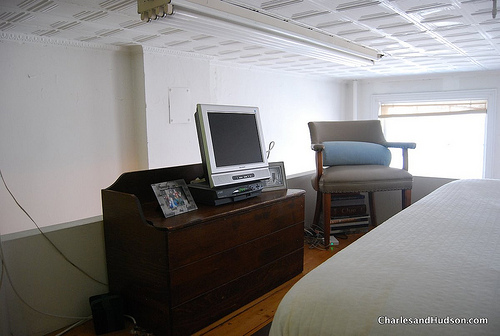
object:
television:
[189, 103, 270, 190]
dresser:
[100, 161, 307, 335]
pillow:
[314, 140, 391, 165]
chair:
[307, 120, 416, 250]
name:
[375, 314, 489, 326]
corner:
[363, 286, 499, 335]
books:
[317, 191, 370, 236]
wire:
[1, 172, 101, 336]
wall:
[1, 32, 347, 335]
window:
[378, 100, 488, 181]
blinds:
[375, 99, 487, 118]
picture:
[161, 185, 190, 209]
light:
[330, 243, 334, 246]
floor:
[33, 235, 371, 336]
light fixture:
[137, 0, 384, 71]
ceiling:
[0, 0, 499, 81]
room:
[0, 1, 500, 335]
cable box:
[187, 178, 264, 207]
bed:
[267, 178, 500, 336]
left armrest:
[382, 139, 417, 172]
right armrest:
[310, 142, 325, 184]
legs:
[310, 189, 412, 250]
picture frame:
[151, 179, 198, 218]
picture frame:
[262, 160, 286, 192]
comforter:
[270, 178, 498, 336]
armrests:
[311, 142, 417, 180]